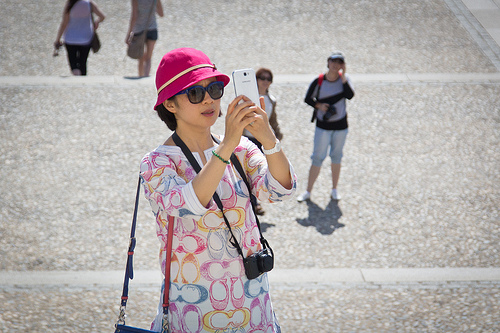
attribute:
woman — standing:
[140, 47, 296, 333]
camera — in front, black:
[231, 68, 262, 116]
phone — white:
[233, 68, 263, 112]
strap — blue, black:
[122, 170, 176, 312]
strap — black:
[171, 130, 270, 259]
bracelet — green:
[211, 148, 231, 166]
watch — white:
[262, 138, 283, 156]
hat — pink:
[152, 46, 230, 112]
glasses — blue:
[172, 80, 227, 105]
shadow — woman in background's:
[294, 197, 347, 236]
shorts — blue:
[311, 126, 350, 168]